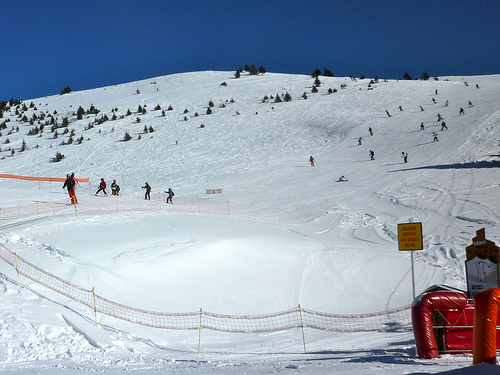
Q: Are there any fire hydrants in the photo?
A: No, there are no fire hydrants.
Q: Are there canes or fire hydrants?
A: No, there are no fire hydrants or canes.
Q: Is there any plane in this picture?
A: No, there are no airplanes.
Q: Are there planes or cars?
A: No, there are no planes or cars.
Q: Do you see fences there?
A: Yes, there is a fence.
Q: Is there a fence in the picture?
A: Yes, there is a fence.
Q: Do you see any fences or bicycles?
A: Yes, there is a fence.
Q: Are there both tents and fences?
A: No, there is a fence but no tents.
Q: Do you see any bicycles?
A: No, there are no bicycles.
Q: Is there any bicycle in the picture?
A: No, there are no bicycles.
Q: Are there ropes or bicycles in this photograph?
A: No, there are no bicycles or ropes.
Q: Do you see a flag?
A: No, there are no flags.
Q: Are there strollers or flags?
A: No, there are no flags or strollers.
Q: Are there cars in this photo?
A: No, there are no cars.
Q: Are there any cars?
A: No, there are no cars.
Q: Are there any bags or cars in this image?
A: No, there are no cars or bags.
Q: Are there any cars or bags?
A: No, there are no cars or bags.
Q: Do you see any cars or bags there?
A: No, there are no cars or bags.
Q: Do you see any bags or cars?
A: No, there are no cars or bags.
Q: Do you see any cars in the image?
A: No, there are no cars.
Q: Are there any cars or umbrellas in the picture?
A: No, there are no cars or umbrellas.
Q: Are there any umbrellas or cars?
A: No, there are no cars or umbrellas.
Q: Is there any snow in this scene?
A: Yes, there is snow.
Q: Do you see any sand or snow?
A: Yes, there is snow.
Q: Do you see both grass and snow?
A: No, there is snow but no grass.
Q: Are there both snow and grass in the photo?
A: No, there is snow but no grass.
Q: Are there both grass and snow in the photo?
A: No, there is snow but no grass.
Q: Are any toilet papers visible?
A: No, there are no toilet papers.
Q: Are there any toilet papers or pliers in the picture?
A: No, there are no toilet papers or pliers.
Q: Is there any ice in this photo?
A: Yes, there is ice.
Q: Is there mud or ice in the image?
A: Yes, there is ice.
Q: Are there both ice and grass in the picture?
A: No, there is ice but no grass.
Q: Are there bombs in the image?
A: No, there are no bombs.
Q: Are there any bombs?
A: No, there are no bombs.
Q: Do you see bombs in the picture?
A: No, there are no bombs.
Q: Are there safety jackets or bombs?
A: No, there are no bombs or safety jackets.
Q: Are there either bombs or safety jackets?
A: No, there are no bombs or safety jackets.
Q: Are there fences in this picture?
A: Yes, there is a fence.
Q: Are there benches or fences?
A: Yes, there is a fence.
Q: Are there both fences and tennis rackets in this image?
A: No, there is a fence but no rackets.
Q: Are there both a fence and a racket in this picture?
A: No, there is a fence but no rackets.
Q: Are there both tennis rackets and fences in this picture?
A: No, there is a fence but no rackets.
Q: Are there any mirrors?
A: No, there are no mirrors.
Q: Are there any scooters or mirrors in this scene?
A: No, there are no mirrors or scooters.